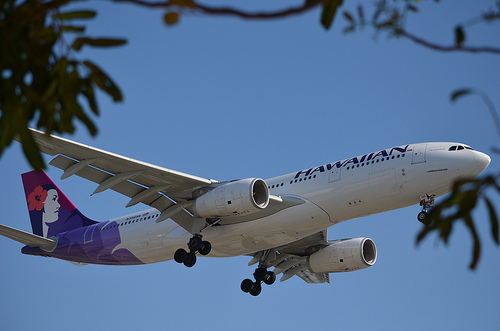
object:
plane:
[1, 117, 492, 297]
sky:
[1, 1, 497, 327]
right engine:
[191, 176, 272, 219]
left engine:
[303, 236, 379, 275]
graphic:
[21, 170, 145, 269]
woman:
[26, 184, 63, 239]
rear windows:
[109, 225, 113, 230]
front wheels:
[415, 209, 435, 226]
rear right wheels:
[172, 248, 189, 264]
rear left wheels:
[239, 278, 256, 294]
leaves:
[0, 0, 56, 40]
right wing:
[2, 114, 217, 236]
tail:
[0, 166, 102, 263]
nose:
[470, 151, 493, 179]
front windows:
[400, 153, 406, 158]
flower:
[27, 184, 48, 211]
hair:
[28, 182, 58, 239]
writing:
[292, 144, 410, 177]